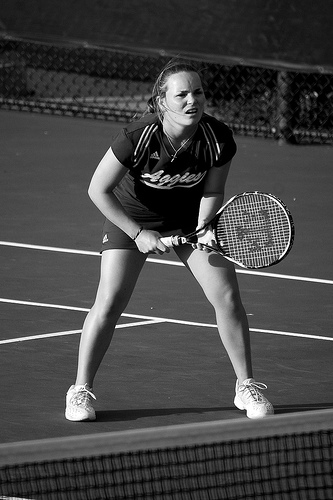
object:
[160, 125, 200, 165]
necklace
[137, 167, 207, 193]
aggies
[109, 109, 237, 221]
shirt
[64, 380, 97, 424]
tennis shoe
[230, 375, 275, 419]
tennis shoe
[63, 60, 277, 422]
woman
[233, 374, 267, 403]
laces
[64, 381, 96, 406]
laces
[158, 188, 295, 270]
racket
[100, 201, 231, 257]
shorts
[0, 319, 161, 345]
line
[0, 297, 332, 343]
line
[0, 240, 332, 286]
line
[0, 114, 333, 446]
tennis court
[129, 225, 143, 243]
band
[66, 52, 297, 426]
tennis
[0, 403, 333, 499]
tennis net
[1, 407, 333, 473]
trim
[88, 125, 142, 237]
arm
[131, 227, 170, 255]
hand